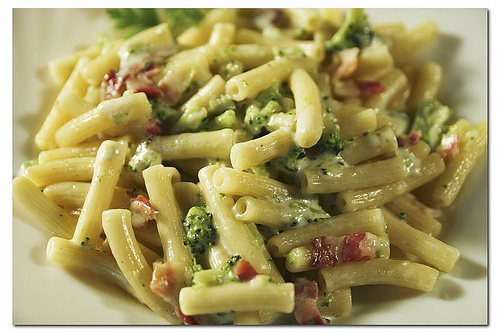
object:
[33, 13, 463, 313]
salad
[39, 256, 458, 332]
plate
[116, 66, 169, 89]
bacon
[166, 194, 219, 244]
broccoli